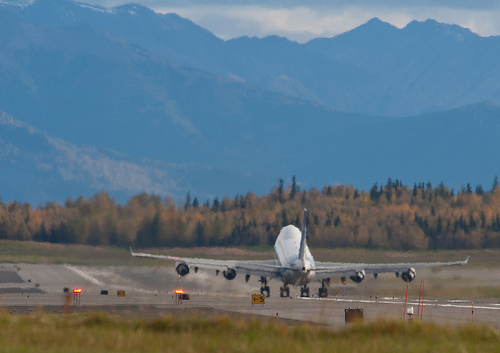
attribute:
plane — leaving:
[125, 204, 472, 301]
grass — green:
[2, 301, 496, 351]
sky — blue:
[207, 4, 499, 39]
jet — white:
[118, 198, 478, 301]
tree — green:
[278, 167, 306, 212]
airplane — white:
[127, 205, 476, 300]